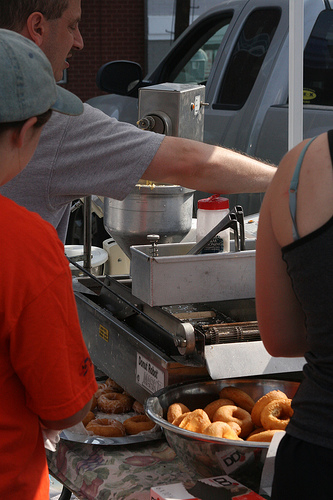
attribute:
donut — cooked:
[82, 415, 125, 435]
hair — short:
[0, 0, 68, 32]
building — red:
[86, 11, 147, 93]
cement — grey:
[112, 27, 126, 28]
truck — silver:
[77, 0, 315, 225]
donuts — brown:
[135, 374, 298, 475]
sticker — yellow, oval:
[290, 91, 314, 101]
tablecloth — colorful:
[46, 443, 227, 499]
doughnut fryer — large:
[84, 194, 253, 379]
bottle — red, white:
[189, 182, 254, 265]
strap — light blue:
[284, 135, 321, 242]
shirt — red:
[2, 196, 102, 437]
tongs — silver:
[188, 214, 263, 253]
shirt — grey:
[38, 97, 155, 246]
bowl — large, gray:
[143, 370, 306, 489]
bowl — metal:
[147, 379, 301, 484]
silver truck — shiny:
[109, 18, 331, 160]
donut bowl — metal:
[141, 373, 298, 480]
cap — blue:
[2, 9, 90, 152]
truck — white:
[94, 6, 329, 193]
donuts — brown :
[164, 384, 290, 459]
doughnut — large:
[261, 398, 290, 426]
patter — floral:
[111, 435, 166, 483]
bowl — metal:
[150, 418, 261, 471]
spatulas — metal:
[191, 201, 246, 255]